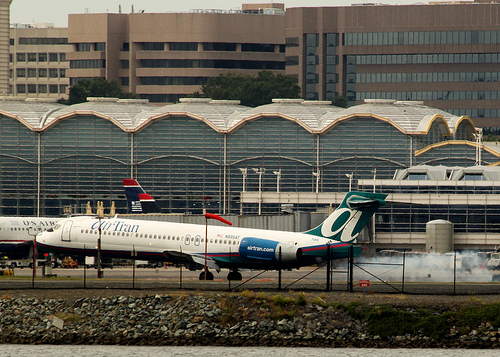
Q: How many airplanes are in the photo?
A: One.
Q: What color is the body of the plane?
A: White.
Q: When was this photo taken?
A: Daytime.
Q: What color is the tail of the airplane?
A: Green.